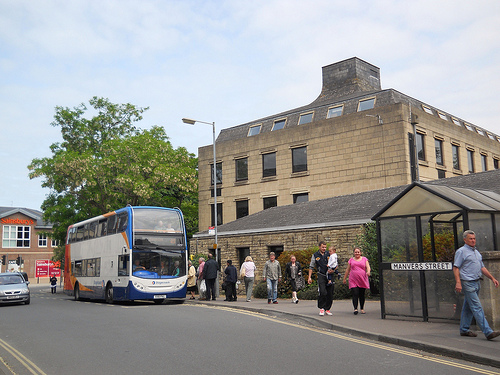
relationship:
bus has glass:
[59, 221, 199, 302] [137, 229, 189, 285]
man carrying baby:
[306, 240, 347, 307] [322, 240, 344, 287]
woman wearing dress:
[343, 236, 374, 314] [346, 258, 372, 290]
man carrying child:
[306, 240, 347, 307] [327, 241, 341, 275]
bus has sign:
[59, 221, 199, 302] [145, 235, 180, 243]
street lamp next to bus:
[170, 107, 228, 160] [59, 221, 199, 302]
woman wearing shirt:
[346, 258, 372, 290] [350, 253, 368, 286]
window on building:
[234, 148, 260, 186] [225, 106, 457, 246]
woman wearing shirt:
[343, 236, 374, 314] [350, 253, 368, 286]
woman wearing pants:
[343, 236, 374, 314] [347, 278, 372, 311]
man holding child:
[306, 240, 347, 307] [327, 241, 341, 275]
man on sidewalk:
[306, 240, 347, 307] [327, 307, 362, 336]